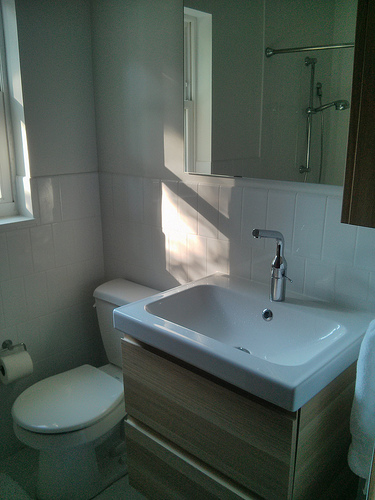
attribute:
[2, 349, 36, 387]
toilet paper — white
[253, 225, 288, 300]
bathroom faucet — chrome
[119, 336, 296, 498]
drawer — wooden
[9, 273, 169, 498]
toilet — white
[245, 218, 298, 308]
fixtures — silver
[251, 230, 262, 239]
faucet nozzle — metal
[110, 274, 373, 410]
sink — white, porcelain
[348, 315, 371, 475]
towel — white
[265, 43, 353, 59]
curtain rod — silver